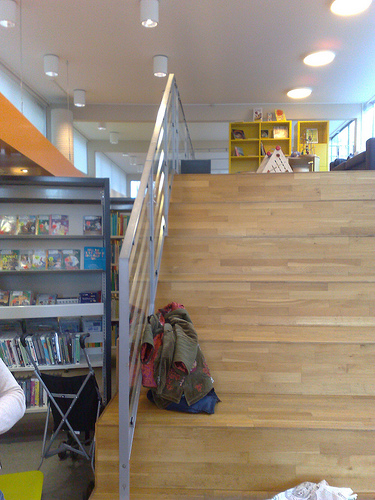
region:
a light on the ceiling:
[295, 48, 334, 68]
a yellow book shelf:
[225, 113, 296, 173]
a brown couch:
[327, 136, 373, 169]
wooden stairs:
[175, 179, 371, 488]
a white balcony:
[99, 69, 208, 413]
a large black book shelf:
[5, 174, 109, 392]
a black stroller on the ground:
[19, 330, 109, 460]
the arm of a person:
[2, 369, 32, 430]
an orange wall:
[5, 103, 87, 177]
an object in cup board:
[25, 382, 93, 492]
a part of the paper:
[281, 464, 347, 498]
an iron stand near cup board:
[102, 335, 149, 497]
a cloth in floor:
[144, 316, 234, 430]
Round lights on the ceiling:
[281, 0, 374, 106]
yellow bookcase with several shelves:
[230, 120, 293, 176]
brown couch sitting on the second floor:
[328, 137, 374, 169]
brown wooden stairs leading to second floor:
[95, 170, 374, 498]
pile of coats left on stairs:
[139, 300, 218, 417]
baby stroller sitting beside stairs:
[17, 329, 101, 466]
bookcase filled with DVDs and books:
[0, 177, 111, 435]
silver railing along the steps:
[118, 74, 195, 498]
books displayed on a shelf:
[0, 202, 105, 239]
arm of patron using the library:
[0, 355, 29, 435]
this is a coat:
[138, 294, 216, 405]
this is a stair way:
[170, 167, 373, 497]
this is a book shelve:
[2, 188, 116, 393]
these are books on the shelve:
[52, 323, 83, 362]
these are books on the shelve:
[36, 330, 60, 368]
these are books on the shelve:
[0, 331, 30, 380]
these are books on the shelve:
[79, 241, 104, 272]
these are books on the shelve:
[20, 240, 46, 267]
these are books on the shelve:
[28, 211, 64, 237]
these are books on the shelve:
[28, 250, 55, 275]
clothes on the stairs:
[91, 271, 244, 427]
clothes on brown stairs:
[142, 281, 214, 396]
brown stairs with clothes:
[105, 289, 254, 450]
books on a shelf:
[17, 199, 194, 388]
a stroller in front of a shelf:
[9, 290, 174, 482]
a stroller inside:
[11, 301, 152, 463]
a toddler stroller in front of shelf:
[29, 308, 189, 479]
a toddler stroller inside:
[13, 296, 138, 495]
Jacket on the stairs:
[125, 281, 231, 418]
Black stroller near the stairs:
[5, 324, 99, 470]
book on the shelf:
[1, 241, 19, 272]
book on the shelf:
[46, 243, 78, 270]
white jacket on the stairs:
[271, 480, 351, 498]